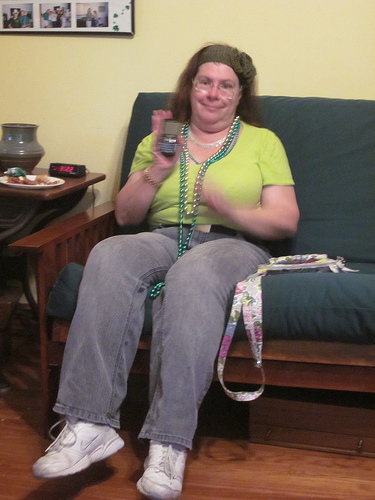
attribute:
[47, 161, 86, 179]
clock — small, black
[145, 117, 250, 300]
necklace — long, green, beaded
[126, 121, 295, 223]
shirt — green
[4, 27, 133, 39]
frame — black, white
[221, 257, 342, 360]
bag — floral, decorated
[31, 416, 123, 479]
shoe — white, tennis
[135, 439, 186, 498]
shoe — white, tennis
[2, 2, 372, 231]
wall — yellow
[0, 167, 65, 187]
plate — white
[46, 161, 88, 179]
alarm clock — black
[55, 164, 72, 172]
numbers — red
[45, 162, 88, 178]
clock — alarm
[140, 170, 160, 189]
bracelet — gold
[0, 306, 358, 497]
floor — brown, hardwood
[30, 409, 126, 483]
sneaker — white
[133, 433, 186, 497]
sneaker — white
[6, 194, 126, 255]
arm — wooden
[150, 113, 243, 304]
necklaces — beaded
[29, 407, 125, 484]
shoes — white, nike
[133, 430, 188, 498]
shoes — white, nike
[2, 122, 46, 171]
vase — grey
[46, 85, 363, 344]
mattress — blue, futon